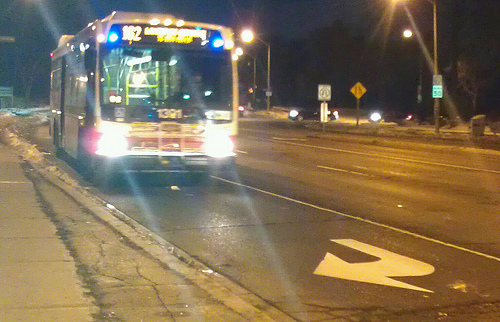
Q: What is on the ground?
A: The arrow sign.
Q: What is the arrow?
A: White.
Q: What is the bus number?
A: 162.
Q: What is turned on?
A: The lights.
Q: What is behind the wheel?
A: The bus driver.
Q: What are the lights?
A: Blue.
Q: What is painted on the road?
A: The turn arrow.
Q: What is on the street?
A: Bus.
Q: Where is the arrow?
A: On the street.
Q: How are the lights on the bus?
A: Turned on.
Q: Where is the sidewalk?
A: Along the street.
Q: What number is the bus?
A: 1391.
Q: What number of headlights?
A: Two.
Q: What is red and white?
A: Bus.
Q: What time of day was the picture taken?
A: At night time.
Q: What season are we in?
A: Winter.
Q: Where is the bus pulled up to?
A: Sidewalk.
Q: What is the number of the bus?
A: 1391.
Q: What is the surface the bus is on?
A: Concrete.